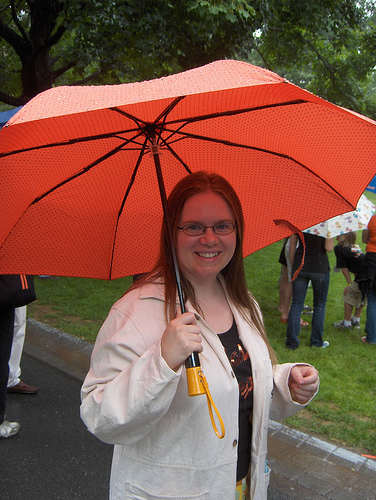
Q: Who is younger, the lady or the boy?
A: The boy is younger than the lady.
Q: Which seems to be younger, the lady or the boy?
A: The boy is younger than the lady.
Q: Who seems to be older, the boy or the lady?
A: The lady is older than the boy.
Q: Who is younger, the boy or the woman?
A: The boy is younger than the woman.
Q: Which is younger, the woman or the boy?
A: The boy is younger than the woman.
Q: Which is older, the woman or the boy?
A: The woman is older than the boy.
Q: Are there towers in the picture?
A: No, there are no towers.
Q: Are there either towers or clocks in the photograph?
A: No, there are no towers or clocks.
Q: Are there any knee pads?
A: No, there are no knee pads.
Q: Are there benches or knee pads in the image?
A: No, there are no knee pads or benches.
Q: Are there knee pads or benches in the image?
A: No, there are no knee pads or benches.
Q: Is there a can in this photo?
A: No, there are no cans.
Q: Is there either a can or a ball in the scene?
A: No, there are no cans or balls.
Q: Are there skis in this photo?
A: No, there are no skis.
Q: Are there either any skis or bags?
A: No, there are no skis or bags.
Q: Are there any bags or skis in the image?
A: No, there are no skis or bags.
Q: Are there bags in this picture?
A: No, there are no bags.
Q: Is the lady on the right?
A: Yes, the lady is on the right of the image.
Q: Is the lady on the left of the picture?
A: No, the lady is on the right of the image.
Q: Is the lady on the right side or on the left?
A: The lady is on the right of the image.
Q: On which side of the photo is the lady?
A: The lady is on the right of the image.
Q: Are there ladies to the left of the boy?
A: Yes, there is a lady to the left of the boy.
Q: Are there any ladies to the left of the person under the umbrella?
A: Yes, there is a lady to the left of the boy.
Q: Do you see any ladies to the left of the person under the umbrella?
A: Yes, there is a lady to the left of the boy.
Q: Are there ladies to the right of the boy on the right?
A: No, the lady is to the left of the boy.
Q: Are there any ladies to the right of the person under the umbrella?
A: No, the lady is to the left of the boy.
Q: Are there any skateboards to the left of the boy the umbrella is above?
A: No, there is a lady to the left of the boy.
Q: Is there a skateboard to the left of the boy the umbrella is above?
A: No, there is a lady to the left of the boy.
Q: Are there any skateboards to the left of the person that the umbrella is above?
A: No, there is a lady to the left of the boy.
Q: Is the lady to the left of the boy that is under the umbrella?
A: Yes, the lady is to the left of the boy.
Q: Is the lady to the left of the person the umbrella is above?
A: Yes, the lady is to the left of the boy.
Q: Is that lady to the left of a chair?
A: No, the lady is to the left of the boy.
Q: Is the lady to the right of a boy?
A: No, the lady is to the left of a boy.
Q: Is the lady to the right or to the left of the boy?
A: The lady is to the left of the boy.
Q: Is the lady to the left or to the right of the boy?
A: The lady is to the left of the boy.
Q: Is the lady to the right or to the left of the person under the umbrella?
A: The lady is to the left of the boy.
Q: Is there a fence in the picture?
A: No, there are no fences.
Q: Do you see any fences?
A: No, there are no fences.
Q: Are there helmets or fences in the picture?
A: No, there are no fences or helmets.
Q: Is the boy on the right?
A: Yes, the boy is on the right of the image.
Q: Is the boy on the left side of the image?
A: No, the boy is on the right of the image.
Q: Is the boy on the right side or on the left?
A: The boy is on the right of the image.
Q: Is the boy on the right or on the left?
A: The boy is on the right of the image.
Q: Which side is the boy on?
A: The boy is on the right of the image.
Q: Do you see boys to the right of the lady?
A: Yes, there is a boy to the right of the lady.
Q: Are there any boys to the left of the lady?
A: No, the boy is to the right of the lady.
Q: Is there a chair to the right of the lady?
A: No, there is a boy to the right of the lady.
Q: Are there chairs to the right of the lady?
A: No, there is a boy to the right of the lady.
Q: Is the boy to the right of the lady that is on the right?
A: Yes, the boy is to the right of the lady.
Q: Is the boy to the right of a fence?
A: No, the boy is to the right of the lady.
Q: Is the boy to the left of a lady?
A: No, the boy is to the right of a lady.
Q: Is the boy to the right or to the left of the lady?
A: The boy is to the right of the lady.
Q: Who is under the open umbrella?
A: The boy is under the umbrella.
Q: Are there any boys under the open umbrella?
A: Yes, there is a boy under the umbrella.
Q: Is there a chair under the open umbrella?
A: No, there is a boy under the umbrella.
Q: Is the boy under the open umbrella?
A: Yes, the boy is under the umbrella.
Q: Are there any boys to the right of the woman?
A: Yes, there is a boy to the right of the woman.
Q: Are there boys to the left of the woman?
A: No, the boy is to the right of the woman.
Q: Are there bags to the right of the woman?
A: No, there is a boy to the right of the woman.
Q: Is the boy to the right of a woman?
A: Yes, the boy is to the right of a woman.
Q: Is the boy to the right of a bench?
A: No, the boy is to the right of a woman.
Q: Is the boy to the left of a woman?
A: No, the boy is to the right of a woman.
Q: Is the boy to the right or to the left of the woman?
A: The boy is to the right of the woman.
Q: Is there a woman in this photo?
A: Yes, there is a woman.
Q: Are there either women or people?
A: Yes, there is a woman.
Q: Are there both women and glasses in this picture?
A: Yes, there are both a woman and glasses.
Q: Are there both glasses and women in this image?
A: Yes, there are both a woman and glasses.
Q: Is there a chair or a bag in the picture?
A: No, there are no bags or chairs.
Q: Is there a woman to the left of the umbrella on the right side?
A: Yes, there is a woman to the left of the umbrella.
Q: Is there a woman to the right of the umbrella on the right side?
A: No, the woman is to the left of the umbrella.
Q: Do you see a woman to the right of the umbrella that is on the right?
A: No, the woman is to the left of the umbrella.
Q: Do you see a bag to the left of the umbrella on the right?
A: No, there is a woman to the left of the umbrella.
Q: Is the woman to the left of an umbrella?
A: Yes, the woman is to the left of an umbrella.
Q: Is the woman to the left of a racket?
A: No, the woman is to the left of an umbrella.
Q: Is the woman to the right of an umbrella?
A: No, the woman is to the left of an umbrella.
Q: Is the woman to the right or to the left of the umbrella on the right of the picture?
A: The woman is to the left of the umbrella.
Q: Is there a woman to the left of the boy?
A: Yes, there is a woman to the left of the boy.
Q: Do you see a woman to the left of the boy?
A: Yes, there is a woman to the left of the boy.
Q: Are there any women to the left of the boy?
A: Yes, there is a woman to the left of the boy.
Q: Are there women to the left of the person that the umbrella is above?
A: Yes, there is a woman to the left of the boy.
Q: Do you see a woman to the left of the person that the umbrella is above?
A: Yes, there is a woman to the left of the boy.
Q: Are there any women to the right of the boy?
A: No, the woman is to the left of the boy.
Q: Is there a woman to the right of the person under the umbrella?
A: No, the woman is to the left of the boy.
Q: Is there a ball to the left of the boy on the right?
A: No, there is a woman to the left of the boy.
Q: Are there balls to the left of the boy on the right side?
A: No, there is a woman to the left of the boy.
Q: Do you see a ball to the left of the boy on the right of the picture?
A: No, there is a woman to the left of the boy.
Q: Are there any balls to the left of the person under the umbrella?
A: No, there is a woman to the left of the boy.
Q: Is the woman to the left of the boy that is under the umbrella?
A: Yes, the woman is to the left of the boy.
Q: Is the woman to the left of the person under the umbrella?
A: Yes, the woman is to the left of the boy.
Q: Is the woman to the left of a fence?
A: No, the woman is to the left of the boy.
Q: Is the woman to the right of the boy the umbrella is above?
A: No, the woman is to the left of the boy.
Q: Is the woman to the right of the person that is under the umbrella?
A: No, the woman is to the left of the boy.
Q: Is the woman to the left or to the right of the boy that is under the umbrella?
A: The woman is to the left of the boy.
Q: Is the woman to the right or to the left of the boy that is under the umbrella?
A: The woman is to the left of the boy.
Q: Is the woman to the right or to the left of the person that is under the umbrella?
A: The woman is to the left of the boy.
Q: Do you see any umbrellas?
A: Yes, there is an umbrella.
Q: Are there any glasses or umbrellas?
A: Yes, there is an umbrella.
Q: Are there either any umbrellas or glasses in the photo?
A: Yes, there is an umbrella.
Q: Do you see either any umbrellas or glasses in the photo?
A: Yes, there is an umbrella.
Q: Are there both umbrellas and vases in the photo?
A: No, there is an umbrella but no vases.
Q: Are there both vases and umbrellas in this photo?
A: No, there is an umbrella but no vases.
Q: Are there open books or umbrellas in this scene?
A: Yes, there is an open umbrella.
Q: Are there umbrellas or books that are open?
A: Yes, the umbrella is open.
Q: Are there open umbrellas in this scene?
A: Yes, there is an open umbrella.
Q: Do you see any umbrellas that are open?
A: Yes, there is an umbrella that is open.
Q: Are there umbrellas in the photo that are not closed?
A: Yes, there is a open umbrella.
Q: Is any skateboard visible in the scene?
A: No, there are no skateboards.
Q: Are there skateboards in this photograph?
A: No, there are no skateboards.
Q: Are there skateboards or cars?
A: No, there are no skateboards or cars.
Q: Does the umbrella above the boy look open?
A: Yes, the umbrella is open.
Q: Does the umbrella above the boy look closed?
A: No, the umbrella is open.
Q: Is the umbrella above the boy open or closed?
A: The umbrella is open.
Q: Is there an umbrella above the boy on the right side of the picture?
A: Yes, there is an umbrella above the boy.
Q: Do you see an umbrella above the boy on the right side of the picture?
A: Yes, there is an umbrella above the boy.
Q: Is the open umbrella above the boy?
A: Yes, the umbrella is above the boy.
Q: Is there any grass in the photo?
A: Yes, there is grass.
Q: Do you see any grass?
A: Yes, there is grass.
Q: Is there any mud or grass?
A: Yes, there is grass.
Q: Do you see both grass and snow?
A: No, there is grass but no snow.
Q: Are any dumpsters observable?
A: No, there are no dumpsters.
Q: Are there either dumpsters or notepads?
A: No, there are no dumpsters or notepads.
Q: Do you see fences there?
A: No, there are no fences.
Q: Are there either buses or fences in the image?
A: No, there are no fences or buses.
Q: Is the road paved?
A: Yes, the road is paved.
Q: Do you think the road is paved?
A: Yes, the road is paved.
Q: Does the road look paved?
A: Yes, the road is paved.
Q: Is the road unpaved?
A: No, the road is paved.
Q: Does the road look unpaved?
A: No, the road is paved.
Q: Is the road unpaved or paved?
A: The road is paved.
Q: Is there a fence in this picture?
A: No, there are no fences.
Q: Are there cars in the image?
A: No, there are no cars.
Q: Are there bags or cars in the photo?
A: No, there are no cars or bags.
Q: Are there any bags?
A: No, there are no bags.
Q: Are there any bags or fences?
A: No, there are no bags or fences.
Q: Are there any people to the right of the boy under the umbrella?
A: Yes, there are people to the right of the boy.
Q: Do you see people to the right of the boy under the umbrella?
A: Yes, there are people to the right of the boy.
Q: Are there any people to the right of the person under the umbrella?
A: Yes, there are people to the right of the boy.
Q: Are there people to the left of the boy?
A: No, the people are to the right of the boy.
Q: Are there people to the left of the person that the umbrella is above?
A: No, the people are to the right of the boy.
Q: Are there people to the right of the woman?
A: Yes, there are people to the right of the woman.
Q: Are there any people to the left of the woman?
A: No, the people are to the right of the woman.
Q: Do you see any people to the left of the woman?
A: No, the people are to the right of the woman.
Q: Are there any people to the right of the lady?
A: Yes, there are people to the right of the lady.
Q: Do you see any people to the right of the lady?
A: Yes, there are people to the right of the lady.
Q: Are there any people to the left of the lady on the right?
A: No, the people are to the right of the lady.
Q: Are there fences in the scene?
A: No, there are no fences.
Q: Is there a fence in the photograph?
A: No, there are no fences.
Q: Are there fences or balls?
A: No, there are no fences or balls.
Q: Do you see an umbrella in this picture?
A: Yes, there is an umbrella.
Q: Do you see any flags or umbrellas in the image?
A: Yes, there is an umbrella.